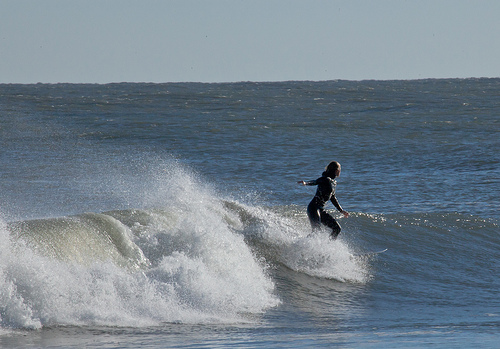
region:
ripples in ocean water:
[57, 101, 125, 150]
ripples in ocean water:
[187, 95, 262, 159]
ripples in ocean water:
[283, 77, 324, 118]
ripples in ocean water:
[354, 112, 416, 179]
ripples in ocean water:
[418, 148, 463, 200]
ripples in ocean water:
[385, 205, 444, 237]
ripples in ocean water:
[377, 253, 465, 318]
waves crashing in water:
[12, 191, 169, 337]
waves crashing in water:
[177, 186, 307, 314]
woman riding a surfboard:
[296, 145, 352, 279]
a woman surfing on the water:
[290, 154, 352, 251]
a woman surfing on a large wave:
[2, 192, 499, 348]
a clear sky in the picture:
[0, 1, 498, 87]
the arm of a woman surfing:
[297, 171, 321, 186]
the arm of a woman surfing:
[328, 187, 353, 218]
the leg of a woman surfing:
[300, 208, 325, 250]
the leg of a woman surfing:
[322, 208, 340, 249]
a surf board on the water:
[272, 239, 390, 262]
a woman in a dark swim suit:
[298, 156, 352, 257]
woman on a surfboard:
[294, 138, 368, 255]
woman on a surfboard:
[291, 147, 356, 260]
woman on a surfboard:
[283, 155, 342, 233]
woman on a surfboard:
[288, 157, 356, 262]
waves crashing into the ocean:
[23, 224, 125, 296]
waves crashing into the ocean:
[85, 220, 177, 317]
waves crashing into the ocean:
[195, 200, 286, 326]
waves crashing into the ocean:
[243, 163, 337, 322]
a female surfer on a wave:
[298, 160, 350, 242]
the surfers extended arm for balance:
[296, 175, 323, 188]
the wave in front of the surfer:
[358, 207, 499, 273]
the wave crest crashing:
[0, 194, 305, 335]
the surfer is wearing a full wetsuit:
[306, 175, 345, 247]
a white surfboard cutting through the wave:
[341, 245, 393, 258]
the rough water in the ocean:
[1, 82, 499, 158]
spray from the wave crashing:
[0, 109, 219, 214]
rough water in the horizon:
[0, 74, 497, 89]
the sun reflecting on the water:
[351, 205, 499, 230]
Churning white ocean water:
[155, 225, 213, 265]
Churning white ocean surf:
[4, 236, 67, 293]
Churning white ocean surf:
[266, 223, 313, 258]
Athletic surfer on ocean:
[295, 155, 352, 238]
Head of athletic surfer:
[323, 156, 344, 176]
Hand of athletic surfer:
[337, 205, 353, 217]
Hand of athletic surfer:
[296, 181, 308, 190]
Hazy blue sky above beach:
[101, 24, 151, 49]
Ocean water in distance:
[202, 108, 262, 125]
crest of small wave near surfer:
[361, 211, 419, 227]